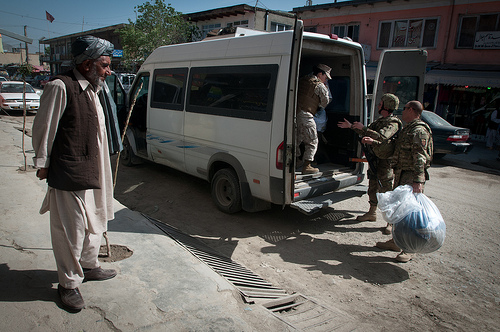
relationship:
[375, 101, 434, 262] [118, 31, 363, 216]
person standing near van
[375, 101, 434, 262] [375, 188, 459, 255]
person donating goods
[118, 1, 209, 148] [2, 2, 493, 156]
tree in background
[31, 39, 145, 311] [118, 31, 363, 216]
person standing near van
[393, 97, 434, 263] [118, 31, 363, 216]
person standing near van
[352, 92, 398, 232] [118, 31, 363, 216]
person standing near van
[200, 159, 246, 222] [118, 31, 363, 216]
tire on van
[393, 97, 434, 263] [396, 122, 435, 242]
person wearing uniform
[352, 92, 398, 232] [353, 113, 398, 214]
person wearing uniform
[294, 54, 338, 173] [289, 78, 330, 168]
person wearing uniform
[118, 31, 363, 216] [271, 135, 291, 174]
van has tail light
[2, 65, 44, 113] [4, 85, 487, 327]
car parked on street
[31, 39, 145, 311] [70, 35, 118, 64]
man has headwrap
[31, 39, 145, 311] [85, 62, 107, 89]
man has beard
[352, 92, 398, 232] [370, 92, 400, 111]
soldier wearing helmet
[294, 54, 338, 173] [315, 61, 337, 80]
soldier wearing hat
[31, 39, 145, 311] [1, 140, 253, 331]
man standing on sidewalk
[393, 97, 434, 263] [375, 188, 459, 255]
soldier holding bag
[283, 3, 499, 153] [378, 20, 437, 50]
building has window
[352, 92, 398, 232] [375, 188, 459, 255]
soldier loading bags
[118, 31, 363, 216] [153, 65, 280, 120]
van has windows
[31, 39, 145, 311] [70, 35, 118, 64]
man wearing turban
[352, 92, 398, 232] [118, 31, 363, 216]
man unloading van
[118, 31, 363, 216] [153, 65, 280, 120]
van has window